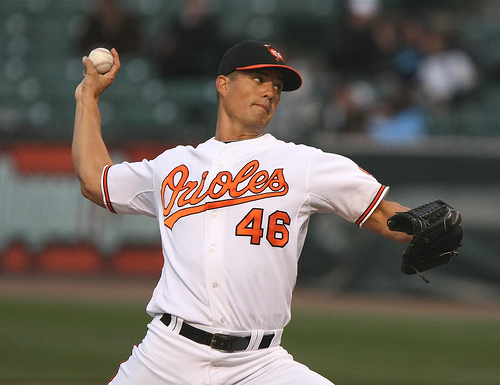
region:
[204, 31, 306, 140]
Player wearing orange and black hat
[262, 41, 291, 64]
Oriole on front of players hat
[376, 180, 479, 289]
Black glove on players left hand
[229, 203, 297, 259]
Number 46 on front of jersey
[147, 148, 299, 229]
Orioles written on front of jersey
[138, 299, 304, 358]
Player wearing black belt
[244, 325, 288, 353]
White belt loops on players pants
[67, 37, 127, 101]
Player holding baseball in hand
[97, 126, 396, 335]
Player wearing white and orange jersey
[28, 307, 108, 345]
Green grass on baseball field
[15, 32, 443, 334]
a baseball player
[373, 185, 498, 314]
a black baseball glove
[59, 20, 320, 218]
a man holding a baseball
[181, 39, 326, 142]
a man wearing a black and red hat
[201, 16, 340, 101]
a black and red hat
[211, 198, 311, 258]
the number 46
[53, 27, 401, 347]
a baseball player wearing a jersey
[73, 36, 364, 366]
a man wearing a black belt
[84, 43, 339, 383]
a man wearing white pants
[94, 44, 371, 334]
a man playing baseball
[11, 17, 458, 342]
this is in a stadium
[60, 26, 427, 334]
this is on a baseball diamond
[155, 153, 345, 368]
the man's jersey is orange and white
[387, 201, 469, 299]
this is a baseball glove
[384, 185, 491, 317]
the glove is black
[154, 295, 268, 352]
the man's belt is black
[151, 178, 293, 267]
the writing is orange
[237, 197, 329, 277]
the number is 46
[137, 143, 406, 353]
the man plays for the orioles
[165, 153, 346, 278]
the jersey says "orioles"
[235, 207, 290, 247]
player number on the jersey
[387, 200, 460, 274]
black baseball glove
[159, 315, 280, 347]
thin black leather belt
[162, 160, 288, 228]
the team name is on the jersey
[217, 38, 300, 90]
black hat with an orange brim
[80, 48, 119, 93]
baseball in the player's hand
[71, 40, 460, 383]
player is about to throw the ball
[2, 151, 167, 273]
orange and white advertisement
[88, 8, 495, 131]
fans in the stands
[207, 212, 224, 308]
white buttons on the jersey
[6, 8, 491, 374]
Photo taken at a baseball game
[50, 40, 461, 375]
Man pitching the ball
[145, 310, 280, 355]
Belt on the uniform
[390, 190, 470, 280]
Glove on the man's left hand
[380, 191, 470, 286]
Black baseball glove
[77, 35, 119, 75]
Baseball in the right hand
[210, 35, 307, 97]
Hat on the man's head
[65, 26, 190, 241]
The pitcher is right handed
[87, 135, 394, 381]
Pitcher's uniform is white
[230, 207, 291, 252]
#46 on the uniform